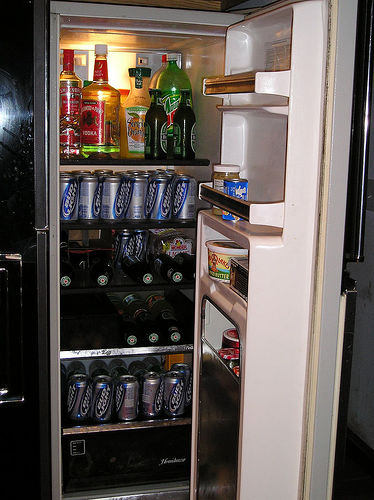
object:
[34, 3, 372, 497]
refrigerator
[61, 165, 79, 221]
beer cans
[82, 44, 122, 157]
vodka bottles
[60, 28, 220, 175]
top shelf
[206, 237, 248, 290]
margarine tub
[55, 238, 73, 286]
beer bottles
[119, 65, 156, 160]
orange juice bottle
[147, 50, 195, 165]
soda bottle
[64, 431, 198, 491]
crisper drawer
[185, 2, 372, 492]
door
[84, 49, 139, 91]
light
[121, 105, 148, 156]
label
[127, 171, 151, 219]
can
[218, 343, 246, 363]
lid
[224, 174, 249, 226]
container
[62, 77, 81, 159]
label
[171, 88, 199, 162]
bottle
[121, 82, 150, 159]
liquid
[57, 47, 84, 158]
items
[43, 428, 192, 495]
bottom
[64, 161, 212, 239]
shelf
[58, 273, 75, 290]
green caps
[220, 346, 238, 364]
jelly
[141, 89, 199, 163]
two bottles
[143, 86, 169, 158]
beer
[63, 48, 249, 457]
no bread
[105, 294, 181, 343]
three bottles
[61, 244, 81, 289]
four bottles